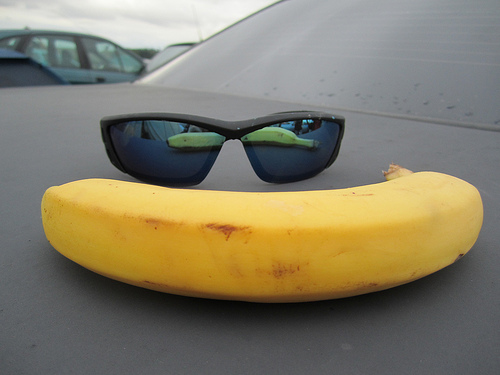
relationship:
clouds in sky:
[1, 0, 280, 52] [124, 14, 174, 34]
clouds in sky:
[1, 0, 280, 52] [165, 4, 178, 32]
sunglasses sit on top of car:
[97, 108, 347, 189] [1, 1, 499, 375]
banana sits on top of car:
[34, 160, 486, 307] [1, 1, 499, 375]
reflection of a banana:
[166, 128, 319, 154] [34, 160, 486, 307]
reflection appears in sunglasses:
[166, 128, 319, 154] [97, 108, 347, 189]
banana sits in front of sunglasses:
[34, 160, 486, 307] [97, 108, 347, 189]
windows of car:
[0, 32, 144, 77] [1, 27, 149, 86]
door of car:
[80, 34, 145, 88] [1, 27, 149, 86]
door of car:
[19, 32, 93, 86] [1, 27, 149, 86]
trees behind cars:
[50, 47, 164, 61] [0, 28, 207, 89]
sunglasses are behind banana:
[97, 108, 347, 189] [34, 160, 486, 307]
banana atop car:
[34, 160, 486, 307] [1, 1, 499, 375]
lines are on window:
[200, 0, 496, 69] [129, 2, 499, 136]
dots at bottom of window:
[219, 75, 499, 129] [129, 2, 499, 136]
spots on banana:
[140, 215, 379, 300] [34, 160, 486, 307]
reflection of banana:
[166, 128, 319, 154] [34, 160, 486, 307]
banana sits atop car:
[34, 160, 486, 307] [1, 1, 499, 375]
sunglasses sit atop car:
[97, 108, 347, 189] [1, 1, 499, 375]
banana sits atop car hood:
[34, 160, 486, 307] [2, 79, 499, 374]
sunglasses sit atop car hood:
[97, 108, 347, 189] [2, 79, 499, 374]